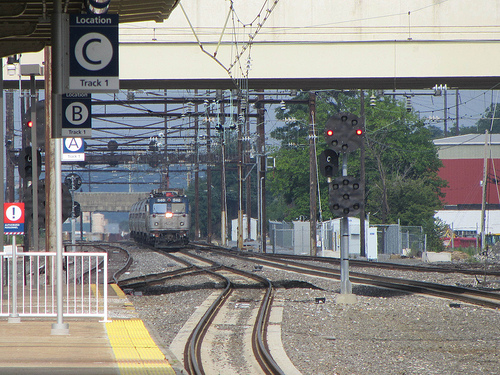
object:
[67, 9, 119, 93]
sign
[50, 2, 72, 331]
pole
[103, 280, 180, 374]
edge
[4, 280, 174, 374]
platform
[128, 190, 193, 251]
train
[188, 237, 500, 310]
tracks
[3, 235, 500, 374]
ground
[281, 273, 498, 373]
rocks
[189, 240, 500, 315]
gravel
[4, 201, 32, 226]
red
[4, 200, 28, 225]
sign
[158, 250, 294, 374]
tracks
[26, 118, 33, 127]
light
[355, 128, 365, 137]
light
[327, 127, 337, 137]
light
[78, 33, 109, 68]
letter c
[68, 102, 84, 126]
circle